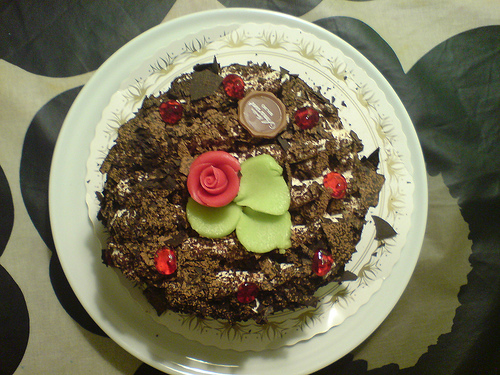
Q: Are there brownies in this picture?
A: Yes, there is a brownie.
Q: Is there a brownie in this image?
A: Yes, there is a brownie.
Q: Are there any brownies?
A: Yes, there is a brownie.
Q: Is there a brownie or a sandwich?
A: Yes, there is a brownie.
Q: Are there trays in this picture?
A: No, there are no trays.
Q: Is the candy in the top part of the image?
A: Yes, the candy is in the top of the image.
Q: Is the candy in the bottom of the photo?
A: No, the candy is in the top of the image.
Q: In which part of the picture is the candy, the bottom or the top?
A: The candy is in the top of the image.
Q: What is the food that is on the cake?
A: The food is a candy.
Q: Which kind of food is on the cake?
A: The food is a candy.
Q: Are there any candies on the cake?
A: Yes, there is a candy on the cake.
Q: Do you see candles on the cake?
A: No, there is a candy on the cake.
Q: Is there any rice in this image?
A: No, there is no rice.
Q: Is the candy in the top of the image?
A: Yes, the candy is in the top of the image.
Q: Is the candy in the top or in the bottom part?
A: The candy is in the top of the image.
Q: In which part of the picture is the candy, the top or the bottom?
A: The candy is in the top of the image.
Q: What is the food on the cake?
A: The food is a candy.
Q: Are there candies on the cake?
A: Yes, there is a candy on the cake.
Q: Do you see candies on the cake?
A: Yes, there is a candy on the cake.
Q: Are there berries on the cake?
A: No, there is a candy on the cake.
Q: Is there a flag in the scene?
A: No, there are no flags.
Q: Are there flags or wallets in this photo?
A: No, there are no flags or wallets.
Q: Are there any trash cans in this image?
A: No, there are no trash cans.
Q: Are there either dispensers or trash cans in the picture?
A: No, there are no trash cans or dispensers.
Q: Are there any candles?
A: No, there are no candles.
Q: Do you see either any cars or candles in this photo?
A: No, there are no candles or cars.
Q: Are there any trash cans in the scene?
A: No, there are no trash cans.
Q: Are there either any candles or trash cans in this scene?
A: No, there are no trash cans or candles.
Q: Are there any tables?
A: Yes, there is a table.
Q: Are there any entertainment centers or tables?
A: Yes, there is a table.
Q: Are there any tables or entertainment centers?
A: Yes, there is a table.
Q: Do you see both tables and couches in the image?
A: No, there is a table but no couches.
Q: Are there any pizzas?
A: No, there are no pizzas.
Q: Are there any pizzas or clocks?
A: No, there are no pizzas or clocks.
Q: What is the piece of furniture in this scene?
A: The piece of furniture is a table.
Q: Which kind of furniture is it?
A: The piece of furniture is a table.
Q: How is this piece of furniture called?
A: That is a table.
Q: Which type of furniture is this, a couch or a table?
A: That is a table.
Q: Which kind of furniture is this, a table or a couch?
A: That is a table.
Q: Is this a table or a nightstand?
A: This is a table.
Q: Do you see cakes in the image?
A: Yes, there is a cake.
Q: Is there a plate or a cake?
A: Yes, there is a cake.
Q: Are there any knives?
A: No, there are no knives.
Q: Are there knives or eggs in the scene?
A: No, there are no knives or eggs.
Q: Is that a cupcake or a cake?
A: That is a cake.